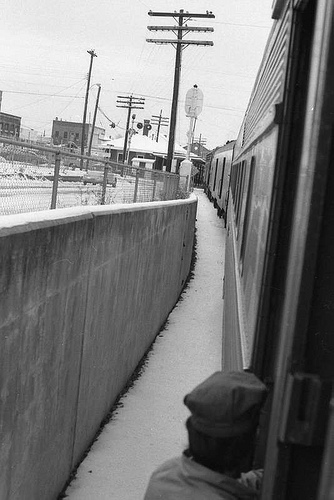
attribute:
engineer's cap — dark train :
[182, 364, 262, 435]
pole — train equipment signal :
[179, 81, 202, 199]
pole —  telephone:
[161, 77, 183, 141]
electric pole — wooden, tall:
[145, 6, 214, 172]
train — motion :
[201, 0, 331, 497]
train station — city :
[3, 127, 225, 492]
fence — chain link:
[0, 135, 189, 213]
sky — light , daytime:
[0, 2, 279, 169]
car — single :
[80, 161, 122, 185]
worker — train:
[141, 369, 269, 498]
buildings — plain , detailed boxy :
[34, 94, 147, 207]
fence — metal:
[14, 139, 72, 201]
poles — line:
[68, 11, 216, 171]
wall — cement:
[127, 203, 204, 290]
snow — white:
[145, 193, 173, 205]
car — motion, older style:
[45, 142, 130, 186]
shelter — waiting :
[149, 142, 197, 180]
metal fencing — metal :
[3, 149, 184, 203]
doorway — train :
[241, 231, 310, 422]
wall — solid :
[5, 200, 198, 497]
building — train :
[94, 133, 202, 187]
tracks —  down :
[201, 187, 244, 256]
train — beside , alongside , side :
[196, 1, 323, 488]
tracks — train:
[209, 191, 223, 303]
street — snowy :
[22, 172, 91, 201]